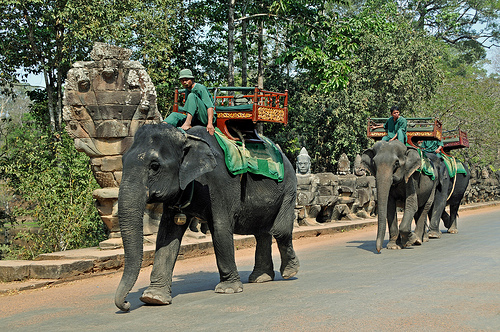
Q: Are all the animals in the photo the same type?
A: Yes, all the animals are elephants.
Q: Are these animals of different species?
A: No, all the animals are elephants.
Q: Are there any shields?
A: No, there are no shields.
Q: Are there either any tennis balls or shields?
A: No, there are no shields or tennis balls.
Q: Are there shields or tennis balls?
A: No, there are no shields or tennis balls.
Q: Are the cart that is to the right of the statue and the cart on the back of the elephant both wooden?
A: Yes, both the cart and the cart are wooden.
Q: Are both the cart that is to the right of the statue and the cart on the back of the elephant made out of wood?
A: Yes, both the cart and the cart are made of wood.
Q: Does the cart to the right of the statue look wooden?
A: Yes, the cart is wooden.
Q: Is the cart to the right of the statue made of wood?
A: Yes, the cart is made of wood.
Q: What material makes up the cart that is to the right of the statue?
A: The cart is made of wood.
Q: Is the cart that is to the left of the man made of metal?
A: No, the cart is made of wood.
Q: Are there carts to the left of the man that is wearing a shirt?
A: Yes, there is a cart to the left of the man.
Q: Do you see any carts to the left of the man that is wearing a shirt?
A: Yes, there is a cart to the left of the man.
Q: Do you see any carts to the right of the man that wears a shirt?
A: No, the cart is to the left of the man.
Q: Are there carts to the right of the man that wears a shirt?
A: No, the cart is to the left of the man.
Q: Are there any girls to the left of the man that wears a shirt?
A: No, there is a cart to the left of the man.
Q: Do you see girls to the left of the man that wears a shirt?
A: No, there is a cart to the left of the man.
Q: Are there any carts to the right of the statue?
A: Yes, there is a cart to the right of the statue.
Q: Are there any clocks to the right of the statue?
A: No, there is a cart to the right of the statue.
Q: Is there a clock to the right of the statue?
A: No, there is a cart to the right of the statue.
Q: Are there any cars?
A: No, there are no cars.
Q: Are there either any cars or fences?
A: No, there are no cars or fences.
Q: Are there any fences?
A: No, there are no fences.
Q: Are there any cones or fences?
A: No, there are no fences or cones.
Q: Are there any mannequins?
A: No, there are no mannequins.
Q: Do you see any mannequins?
A: No, there are no mannequins.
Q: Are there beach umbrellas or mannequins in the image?
A: No, there are no mannequins or beach umbrellas.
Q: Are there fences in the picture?
A: No, there are no fences.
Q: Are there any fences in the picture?
A: No, there are no fences.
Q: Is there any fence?
A: No, there are no fences.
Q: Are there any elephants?
A: Yes, there is an elephant.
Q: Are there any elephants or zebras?
A: Yes, there is an elephant.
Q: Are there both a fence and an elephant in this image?
A: No, there is an elephant but no fences.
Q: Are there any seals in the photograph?
A: No, there are no seals.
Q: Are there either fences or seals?
A: No, there are no seals or fences.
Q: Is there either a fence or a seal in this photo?
A: No, there are no seals or fences.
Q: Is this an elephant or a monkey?
A: This is an elephant.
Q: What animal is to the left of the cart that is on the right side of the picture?
A: The animal is an elephant.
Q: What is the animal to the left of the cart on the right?
A: The animal is an elephant.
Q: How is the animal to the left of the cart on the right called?
A: The animal is an elephant.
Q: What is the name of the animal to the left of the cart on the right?
A: The animal is an elephant.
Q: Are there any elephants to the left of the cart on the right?
A: Yes, there is an elephant to the left of the cart.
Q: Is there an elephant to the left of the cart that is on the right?
A: Yes, there is an elephant to the left of the cart.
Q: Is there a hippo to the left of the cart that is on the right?
A: No, there is an elephant to the left of the cart.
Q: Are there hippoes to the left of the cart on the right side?
A: No, there is an elephant to the left of the cart.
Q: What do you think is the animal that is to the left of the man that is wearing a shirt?
A: The animal is an elephant.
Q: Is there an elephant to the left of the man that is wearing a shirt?
A: Yes, there is an elephant to the left of the man.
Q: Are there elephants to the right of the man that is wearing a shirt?
A: No, the elephant is to the left of the man.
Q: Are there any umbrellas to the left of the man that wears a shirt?
A: No, there is an elephant to the left of the man.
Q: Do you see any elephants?
A: Yes, there is an elephant.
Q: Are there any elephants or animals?
A: Yes, there is an elephant.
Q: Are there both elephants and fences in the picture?
A: No, there is an elephant but no fences.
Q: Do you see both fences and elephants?
A: No, there is an elephant but no fences.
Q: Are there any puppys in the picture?
A: No, there are no puppys.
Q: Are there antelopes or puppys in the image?
A: No, there are no puppys or antelopes.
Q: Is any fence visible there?
A: No, there are no fences.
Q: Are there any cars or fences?
A: No, there are no fences or cars.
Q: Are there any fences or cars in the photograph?
A: No, there are no fences or cars.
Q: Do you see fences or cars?
A: No, there are no fences or cars.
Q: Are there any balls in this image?
A: No, there are no balls.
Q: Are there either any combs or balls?
A: No, there are no balls or combs.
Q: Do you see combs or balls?
A: No, there are no balls or combs.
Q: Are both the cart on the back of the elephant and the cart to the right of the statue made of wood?
A: Yes, both the cart and the cart are made of wood.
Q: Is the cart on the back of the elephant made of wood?
A: Yes, the cart is made of wood.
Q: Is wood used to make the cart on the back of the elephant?
A: Yes, the cart is made of wood.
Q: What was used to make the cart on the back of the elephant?
A: The cart is made of wood.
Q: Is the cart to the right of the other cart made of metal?
A: No, the cart is made of wood.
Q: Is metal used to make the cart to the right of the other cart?
A: No, the cart is made of wood.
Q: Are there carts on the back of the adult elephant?
A: Yes, there is a cart on the back of the elephant.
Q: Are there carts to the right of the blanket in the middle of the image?
A: Yes, there is a cart to the right of the blanket.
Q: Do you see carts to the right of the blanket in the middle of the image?
A: Yes, there is a cart to the right of the blanket.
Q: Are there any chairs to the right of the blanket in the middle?
A: No, there is a cart to the right of the blanket.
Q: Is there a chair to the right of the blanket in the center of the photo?
A: No, there is a cart to the right of the blanket.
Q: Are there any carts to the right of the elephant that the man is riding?
A: Yes, there is a cart to the right of the elephant.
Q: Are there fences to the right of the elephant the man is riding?
A: No, there is a cart to the right of the elephant.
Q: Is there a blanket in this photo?
A: Yes, there is a blanket.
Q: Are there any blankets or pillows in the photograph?
A: Yes, there is a blanket.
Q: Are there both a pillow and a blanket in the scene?
A: No, there is a blanket but no pillows.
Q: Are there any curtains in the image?
A: No, there are no curtains.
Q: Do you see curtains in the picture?
A: No, there are no curtains.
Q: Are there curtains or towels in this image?
A: No, there are no curtains or towels.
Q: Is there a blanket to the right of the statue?
A: Yes, there is a blanket to the right of the statue.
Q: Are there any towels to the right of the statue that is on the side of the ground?
A: No, there is a blanket to the right of the statue.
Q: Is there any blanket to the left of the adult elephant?
A: Yes, there is a blanket to the left of the elephant.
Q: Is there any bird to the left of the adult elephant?
A: No, there is a blanket to the left of the elephant.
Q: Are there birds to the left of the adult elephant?
A: No, there is a blanket to the left of the elephant.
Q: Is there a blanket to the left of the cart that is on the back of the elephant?
A: Yes, there is a blanket to the left of the cart.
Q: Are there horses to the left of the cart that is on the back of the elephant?
A: No, there is a blanket to the left of the cart.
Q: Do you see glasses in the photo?
A: No, there are no glasses.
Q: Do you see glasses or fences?
A: No, there are no glasses or fences.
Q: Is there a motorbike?
A: No, there are no motorcycles.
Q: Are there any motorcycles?
A: No, there are no motorcycles.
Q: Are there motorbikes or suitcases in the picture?
A: No, there are no motorbikes or suitcases.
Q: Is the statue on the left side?
A: Yes, the statue is on the left of the image.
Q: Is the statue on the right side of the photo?
A: No, the statue is on the left of the image.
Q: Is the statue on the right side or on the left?
A: The statue is on the left of the image.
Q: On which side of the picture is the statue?
A: The statue is on the left of the image.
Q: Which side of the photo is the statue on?
A: The statue is on the left of the image.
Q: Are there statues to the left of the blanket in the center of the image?
A: Yes, there is a statue to the left of the blanket.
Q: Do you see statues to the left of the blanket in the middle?
A: Yes, there is a statue to the left of the blanket.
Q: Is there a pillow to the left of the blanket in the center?
A: No, there is a statue to the left of the blanket.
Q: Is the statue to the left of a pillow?
A: No, the statue is to the left of the blanket.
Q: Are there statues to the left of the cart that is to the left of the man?
A: Yes, there is a statue to the left of the cart.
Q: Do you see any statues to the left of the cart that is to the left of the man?
A: Yes, there is a statue to the left of the cart.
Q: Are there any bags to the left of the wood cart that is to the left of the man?
A: No, there is a statue to the left of the cart.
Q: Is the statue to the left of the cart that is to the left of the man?
A: Yes, the statue is to the left of the cart.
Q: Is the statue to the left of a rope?
A: No, the statue is to the left of the cart.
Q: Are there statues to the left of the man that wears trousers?
A: Yes, there is a statue to the left of the man.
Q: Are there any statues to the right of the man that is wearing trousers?
A: No, the statue is to the left of the man.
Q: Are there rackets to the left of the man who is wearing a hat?
A: No, there is a statue to the left of the man.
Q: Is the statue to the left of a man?
A: Yes, the statue is to the left of a man.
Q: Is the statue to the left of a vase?
A: No, the statue is to the left of a man.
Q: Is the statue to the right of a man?
A: No, the statue is to the left of a man.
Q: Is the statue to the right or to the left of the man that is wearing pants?
A: The statue is to the left of the man.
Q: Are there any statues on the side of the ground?
A: Yes, there is a statue on the side of the ground.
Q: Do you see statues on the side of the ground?
A: Yes, there is a statue on the side of the ground.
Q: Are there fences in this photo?
A: No, there are no fences.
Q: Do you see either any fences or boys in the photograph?
A: No, there are no fences or boys.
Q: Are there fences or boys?
A: No, there are no fences or boys.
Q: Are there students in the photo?
A: No, there are no students.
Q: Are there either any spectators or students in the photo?
A: No, there are no students or spectators.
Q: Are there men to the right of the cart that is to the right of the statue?
A: Yes, there is a man to the right of the cart.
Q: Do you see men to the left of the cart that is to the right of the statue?
A: No, the man is to the right of the cart.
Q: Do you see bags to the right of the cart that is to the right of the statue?
A: No, there is a man to the right of the cart.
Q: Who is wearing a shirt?
A: The man is wearing a shirt.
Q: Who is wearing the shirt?
A: The man is wearing a shirt.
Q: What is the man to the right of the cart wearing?
A: The man is wearing a shirt.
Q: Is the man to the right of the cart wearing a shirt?
A: Yes, the man is wearing a shirt.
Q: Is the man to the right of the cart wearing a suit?
A: No, the man is wearing a shirt.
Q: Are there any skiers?
A: No, there are no skiers.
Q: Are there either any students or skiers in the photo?
A: No, there are no skiers or students.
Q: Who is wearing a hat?
A: The man is wearing a hat.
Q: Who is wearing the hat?
A: The man is wearing a hat.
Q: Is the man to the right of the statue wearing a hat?
A: Yes, the man is wearing a hat.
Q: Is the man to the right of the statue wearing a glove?
A: No, the man is wearing a hat.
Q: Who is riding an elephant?
A: The man is riding an elephant.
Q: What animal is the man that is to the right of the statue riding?
A: The man is riding an elephant.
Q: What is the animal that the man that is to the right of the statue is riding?
A: The animal is an elephant.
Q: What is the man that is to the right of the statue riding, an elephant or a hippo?
A: The man is riding an elephant.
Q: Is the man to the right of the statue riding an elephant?
A: Yes, the man is riding an elephant.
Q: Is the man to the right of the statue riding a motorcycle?
A: No, the man is riding an elephant.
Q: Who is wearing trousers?
A: The man is wearing trousers.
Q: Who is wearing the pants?
A: The man is wearing trousers.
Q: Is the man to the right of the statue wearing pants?
A: Yes, the man is wearing pants.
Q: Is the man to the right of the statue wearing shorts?
A: No, the man is wearing pants.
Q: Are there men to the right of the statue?
A: Yes, there is a man to the right of the statue.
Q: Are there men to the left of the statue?
A: No, the man is to the right of the statue.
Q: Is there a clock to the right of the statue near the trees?
A: No, there is a man to the right of the statue.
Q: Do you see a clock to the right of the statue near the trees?
A: No, there is a man to the right of the statue.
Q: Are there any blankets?
A: Yes, there is a blanket.